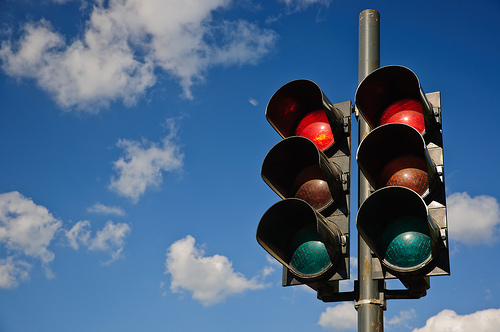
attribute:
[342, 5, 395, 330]
pole — black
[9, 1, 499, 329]
sky — deep blue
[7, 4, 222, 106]
clouds — white, wispy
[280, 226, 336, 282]
light — unlit, green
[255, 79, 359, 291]
light — traffic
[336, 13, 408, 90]
pole — rusted, metal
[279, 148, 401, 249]
cases — black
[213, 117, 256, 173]
sky — blue 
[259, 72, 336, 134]
casing — Light 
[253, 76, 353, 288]
stop light — red, electric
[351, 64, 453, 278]
stop light — red, electric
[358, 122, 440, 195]
yield light — yellow, electric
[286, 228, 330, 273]
green light — electric, go